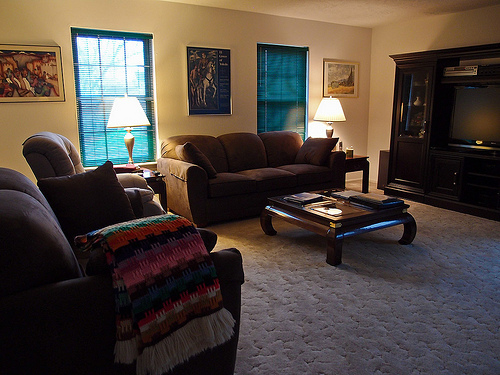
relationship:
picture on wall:
[321, 52, 372, 98] [316, 40, 373, 111]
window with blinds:
[247, 30, 315, 153] [257, 42, 307, 143]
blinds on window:
[72, 34, 155, 170] [70, 27, 159, 168]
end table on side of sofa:
[104, 154, 180, 228] [146, 120, 340, 236]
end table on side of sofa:
[306, 136, 375, 199] [146, 120, 340, 236]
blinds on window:
[71, 27, 156, 168] [70, 27, 159, 168]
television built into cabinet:
[442, 89, 498, 154] [370, 42, 499, 216]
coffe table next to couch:
[259, 188, 417, 268] [153, 125, 350, 225]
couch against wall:
[153, 125, 350, 225] [133, 1, 354, 160]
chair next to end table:
[22, 130, 167, 220] [111, 162, 169, 209]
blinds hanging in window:
[260, 47, 304, 130] [254, 41, 310, 137]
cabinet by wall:
[385, 43, 500, 223] [353, 3, 496, 188]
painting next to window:
[3, 42, 66, 108] [65, 25, 160, 172]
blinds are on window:
[260, 47, 304, 130] [252, 40, 308, 134]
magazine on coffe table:
[284, 190, 329, 205] [259, 188, 417, 268]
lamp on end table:
[106, 96, 151, 170] [113, 167, 168, 214]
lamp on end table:
[306, 91, 349, 149] [330, 154, 369, 194]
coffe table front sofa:
[253, 185, 420, 272] [157, 125, 367, 228]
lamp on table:
[106, 96, 151, 170] [113, 164, 153, 185]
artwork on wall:
[187, 46, 233, 116] [161, 9, 255, 132]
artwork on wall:
[187, 46, 233, 116] [46, 6, 377, 176]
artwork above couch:
[187, 46, 233, 116] [165, 131, 349, 221]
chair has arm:
[1, 164, 250, 373] [69, 253, 264, 372]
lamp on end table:
[100, 88, 156, 187] [116, 157, 178, 220]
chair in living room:
[25, 133, 172, 250] [14, 51, 497, 364]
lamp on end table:
[313, 98, 347, 152] [330, 154, 369, 194]